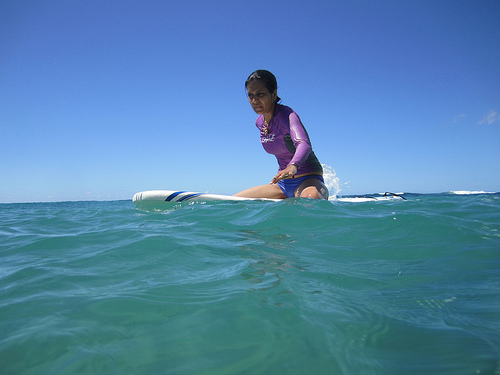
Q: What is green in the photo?
A: The water.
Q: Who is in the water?
A: The girl.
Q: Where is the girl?
A: On the surfboard.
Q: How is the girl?
A: She is floating.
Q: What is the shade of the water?
A: Blue and green.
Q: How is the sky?
A: Clear.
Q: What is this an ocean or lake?
A: Ocean.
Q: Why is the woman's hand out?
A: Balancing.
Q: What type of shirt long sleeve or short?
A: Long sleeve.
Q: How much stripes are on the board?
A: 2.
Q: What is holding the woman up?
A: Surfboard.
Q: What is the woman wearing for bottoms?
A: Bikini bottom.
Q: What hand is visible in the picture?
A: Left.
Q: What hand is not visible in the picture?
A: Right.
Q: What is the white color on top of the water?
A: Wave.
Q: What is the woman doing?
A: Surfing.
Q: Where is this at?
A: Ocean.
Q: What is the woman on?
A: A surfboard.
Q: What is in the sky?
A: Nothing.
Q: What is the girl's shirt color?
A: Purple.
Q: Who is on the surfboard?
A: A woman.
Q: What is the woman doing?
A: Sitting on the surfboard.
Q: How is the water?
A: Calm.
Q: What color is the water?
A: Blue.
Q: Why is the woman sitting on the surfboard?
A: She's waiting for a wave.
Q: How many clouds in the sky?
A: None.